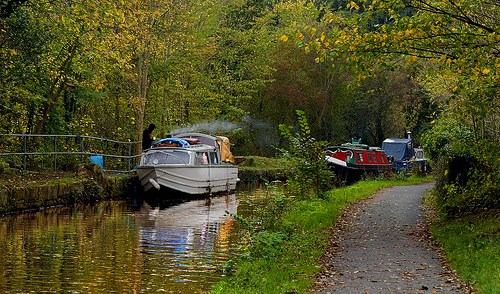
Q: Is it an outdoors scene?
A: Yes, it is outdoors.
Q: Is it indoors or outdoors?
A: It is outdoors.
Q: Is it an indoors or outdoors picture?
A: It is outdoors.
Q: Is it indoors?
A: No, it is outdoors.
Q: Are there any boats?
A: Yes, there is a boat.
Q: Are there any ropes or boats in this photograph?
A: Yes, there is a boat.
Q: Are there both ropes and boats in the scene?
A: No, there is a boat but no ropes.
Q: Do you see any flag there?
A: No, there are no flags.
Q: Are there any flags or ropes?
A: No, there are no flags or ropes.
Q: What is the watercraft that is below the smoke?
A: The watercraft is a boat.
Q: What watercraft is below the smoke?
A: The watercraft is a boat.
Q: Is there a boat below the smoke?
A: Yes, there is a boat below the smoke.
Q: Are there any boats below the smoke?
A: Yes, there is a boat below the smoke.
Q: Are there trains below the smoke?
A: No, there is a boat below the smoke.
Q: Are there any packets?
A: No, there are no packets.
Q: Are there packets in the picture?
A: No, there are no packets.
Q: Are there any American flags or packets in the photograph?
A: No, there are no packets or American flags.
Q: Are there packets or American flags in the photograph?
A: No, there are no packets or American flags.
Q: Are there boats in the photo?
A: Yes, there is a boat.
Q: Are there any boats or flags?
A: Yes, there is a boat.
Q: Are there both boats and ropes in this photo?
A: No, there is a boat but no ropes.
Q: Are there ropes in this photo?
A: No, there are no ropes.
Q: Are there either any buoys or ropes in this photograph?
A: No, there are no ropes or buoys.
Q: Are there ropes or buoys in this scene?
A: No, there are no ropes or buoys.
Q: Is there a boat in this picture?
A: Yes, there is a boat.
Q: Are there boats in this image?
A: Yes, there is a boat.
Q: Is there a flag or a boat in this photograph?
A: Yes, there is a boat.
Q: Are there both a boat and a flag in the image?
A: No, there is a boat but no flags.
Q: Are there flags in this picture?
A: No, there are no flags.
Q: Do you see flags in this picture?
A: No, there are no flags.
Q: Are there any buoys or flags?
A: No, there are no flags or buoys.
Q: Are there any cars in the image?
A: No, there are no cars.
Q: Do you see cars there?
A: No, there are no cars.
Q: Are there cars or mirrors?
A: No, there are no cars or mirrors.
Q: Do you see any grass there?
A: Yes, there is grass.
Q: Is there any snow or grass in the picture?
A: Yes, there is grass.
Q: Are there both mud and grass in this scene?
A: No, there is grass but no mud.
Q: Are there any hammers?
A: No, there are no hammers.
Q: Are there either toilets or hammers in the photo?
A: No, there are no hammers or toilets.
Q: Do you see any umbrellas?
A: No, there are no umbrellas.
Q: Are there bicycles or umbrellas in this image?
A: No, there are no umbrellas or bicycles.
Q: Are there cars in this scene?
A: No, there are no cars.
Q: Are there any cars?
A: No, there are no cars.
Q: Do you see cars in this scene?
A: No, there are no cars.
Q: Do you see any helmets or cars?
A: No, there are no cars or helmets.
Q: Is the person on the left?
A: Yes, the person is on the left of the image.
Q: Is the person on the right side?
A: No, the person is on the left of the image.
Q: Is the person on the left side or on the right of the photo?
A: The person is on the left of the image.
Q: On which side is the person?
A: The person is on the left of the image.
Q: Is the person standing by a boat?
A: Yes, the person is standing by a boat.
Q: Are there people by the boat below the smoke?
A: Yes, there is a person by the boat.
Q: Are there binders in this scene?
A: No, there are no binders.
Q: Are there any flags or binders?
A: No, there are no binders or flags.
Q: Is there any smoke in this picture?
A: Yes, there is smoke.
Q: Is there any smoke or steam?
A: Yes, there is smoke.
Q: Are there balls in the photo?
A: No, there are no balls.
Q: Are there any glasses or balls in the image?
A: No, there are no balls or glasses.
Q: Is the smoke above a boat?
A: Yes, the smoke is above a boat.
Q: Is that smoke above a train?
A: No, the smoke is above a boat.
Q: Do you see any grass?
A: Yes, there is grass.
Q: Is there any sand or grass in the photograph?
A: Yes, there is grass.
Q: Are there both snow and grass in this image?
A: No, there is grass but no snow.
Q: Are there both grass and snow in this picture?
A: No, there is grass but no snow.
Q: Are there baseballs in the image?
A: No, there are no baseballs.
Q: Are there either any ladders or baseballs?
A: No, there are no baseballs or ladders.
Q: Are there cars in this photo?
A: No, there are no cars.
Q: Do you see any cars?
A: No, there are no cars.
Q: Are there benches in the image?
A: No, there are no benches.